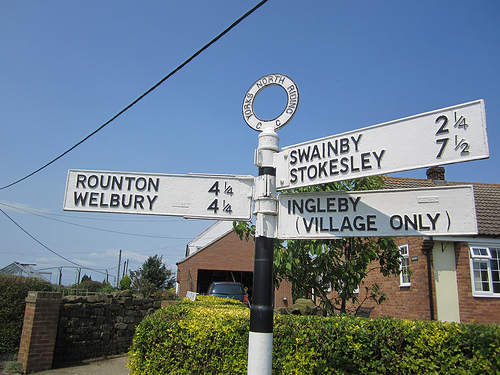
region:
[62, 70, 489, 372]
Pole with signs at intersection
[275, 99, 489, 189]
White sign on pole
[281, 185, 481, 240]
Sign pointing to the right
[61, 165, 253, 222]
Sign pointing to the left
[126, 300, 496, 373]
Short green and yellow fence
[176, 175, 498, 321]
Building made of bricks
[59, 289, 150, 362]
Fence made of stones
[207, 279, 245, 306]
Car parked at garage door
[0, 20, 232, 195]
Electric wire in air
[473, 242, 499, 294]
White window on building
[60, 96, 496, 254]
white street signs with black lettering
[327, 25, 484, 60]
clear blue sky with no clouds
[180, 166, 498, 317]
brick building with white windows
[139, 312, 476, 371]
manicured green hedges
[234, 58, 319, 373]
black and white pole with sign attached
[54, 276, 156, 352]
grey stone wall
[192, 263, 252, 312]
car parked in front of building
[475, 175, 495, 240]
brown shingles roof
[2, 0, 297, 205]
black electrical wires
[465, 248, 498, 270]
top of winddow is open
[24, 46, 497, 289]
a street sign for directions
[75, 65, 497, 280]
this street sign is white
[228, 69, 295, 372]
a pole for the street sign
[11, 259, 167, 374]
a wall next to a house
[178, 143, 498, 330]
a home behind the street sign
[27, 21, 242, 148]
a blue sky above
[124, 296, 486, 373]
bushes behind the street sign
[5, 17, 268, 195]
a power line over the area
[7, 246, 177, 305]
wiring in the area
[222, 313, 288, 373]
this part of the pole is white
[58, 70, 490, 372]
three signs on a white and black pole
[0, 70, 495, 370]
white signs on a sidewalk in front of a house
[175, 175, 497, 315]
a brick home behind the white signs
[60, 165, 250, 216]
Rounton and Welbury sign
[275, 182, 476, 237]
Ingleby sign on a white and black pole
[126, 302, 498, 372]
green trimmed bushes behind the signs on a pole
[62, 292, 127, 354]
a brick retaining wall beside the driveway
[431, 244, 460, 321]
a white door on the brick house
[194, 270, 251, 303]
an opened garage door on the side of the house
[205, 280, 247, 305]
a green SUV parked in front of the garage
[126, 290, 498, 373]
the bushes in front of the brick house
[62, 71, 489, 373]
the signs on the pole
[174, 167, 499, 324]
the brick house behind the bushes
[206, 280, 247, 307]
the vehicle parked in the garage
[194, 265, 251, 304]
the garage to the house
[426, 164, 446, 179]
the chimney on the roof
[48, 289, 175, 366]
the stone wall near the garage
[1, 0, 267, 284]
the wires in the sky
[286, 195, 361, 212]
the word INGLEBY on the street sign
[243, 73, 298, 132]
the circle at the top of the pole